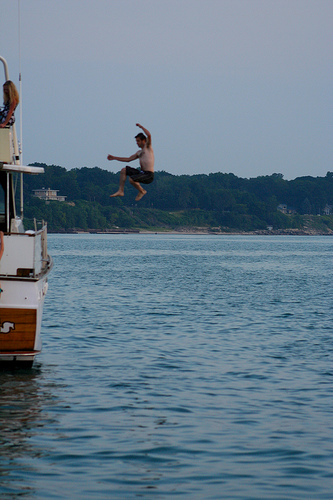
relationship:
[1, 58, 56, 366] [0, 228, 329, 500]
boat in water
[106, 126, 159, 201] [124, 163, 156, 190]
person wearing pants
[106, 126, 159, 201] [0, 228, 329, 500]
person jumping into water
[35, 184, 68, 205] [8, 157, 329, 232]
home on a hill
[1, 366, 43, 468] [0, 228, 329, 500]
reflection on water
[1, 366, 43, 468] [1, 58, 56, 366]
reflection of boat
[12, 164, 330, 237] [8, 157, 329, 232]
trees on hill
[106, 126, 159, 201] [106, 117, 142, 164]
person has hands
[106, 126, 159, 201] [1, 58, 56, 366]
person jumped off boat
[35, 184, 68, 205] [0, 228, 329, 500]
house above water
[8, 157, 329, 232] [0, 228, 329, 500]
hill along water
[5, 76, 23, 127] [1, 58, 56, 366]
woman sitting on a boat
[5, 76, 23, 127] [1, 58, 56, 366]
woman on back of boat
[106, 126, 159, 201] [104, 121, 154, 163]
person has arms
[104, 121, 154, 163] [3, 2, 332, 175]
arms in sky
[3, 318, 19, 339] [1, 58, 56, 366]
s on back of boat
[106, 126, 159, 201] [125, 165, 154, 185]
person wearing pants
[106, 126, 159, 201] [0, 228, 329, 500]
person above water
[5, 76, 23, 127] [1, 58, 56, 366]
woman on upper level of boat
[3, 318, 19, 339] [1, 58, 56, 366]
s on back side of boat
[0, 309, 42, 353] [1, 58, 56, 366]
wood grain on back of boat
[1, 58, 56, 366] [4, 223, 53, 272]
boat has rail